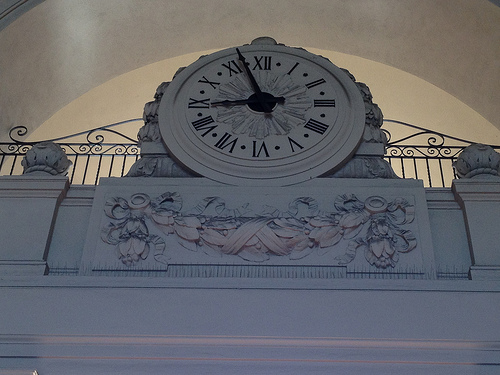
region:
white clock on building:
[185, 57, 335, 179]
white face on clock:
[171, 51, 336, 178]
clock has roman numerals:
[175, 57, 326, 179]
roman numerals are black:
[198, 53, 323, 175]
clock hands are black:
[195, 54, 315, 165]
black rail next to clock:
[365, 111, 469, 202]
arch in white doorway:
[8, 70, 479, 140]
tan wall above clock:
[8, 0, 469, 70]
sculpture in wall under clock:
[105, 161, 403, 276]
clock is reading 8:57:
[194, 57, 309, 167]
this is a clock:
[175, 38, 360, 174]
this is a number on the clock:
[277, 125, 306, 160]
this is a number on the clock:
[304, 111, 336, 139]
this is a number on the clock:
[309, 91, 351, 116]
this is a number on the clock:
[298, 73, 340, 93]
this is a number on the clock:
[281, 49, 308, 85]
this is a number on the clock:
[241, 42, 278, 82]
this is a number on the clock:
[217, 45, 247, 78]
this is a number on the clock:
[181, 90, 221, 115]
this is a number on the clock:
[211, 129, 238, 156]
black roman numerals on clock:
[183, 53, 335, 153]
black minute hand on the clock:
[233, 47, 272, 116]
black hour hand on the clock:
[203, 88, 283, 115]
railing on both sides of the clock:
[11, 120, 483, 177]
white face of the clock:
[183, 55, 357, 162]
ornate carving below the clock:
[104, 184, 414, 268]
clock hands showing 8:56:
[175, 44, 290, 121]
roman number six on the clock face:
[248, 138, 270, 161]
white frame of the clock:
[120, 38, 400, 185]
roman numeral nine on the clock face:
[185, 92, 212, 114]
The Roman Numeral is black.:
[220, 56, 245, 81]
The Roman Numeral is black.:
[191, 70, 222, 90]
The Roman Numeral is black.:
[178, 93, 215, 112]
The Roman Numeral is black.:
[186, 113, 220, 144]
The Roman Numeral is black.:
[211, 127, 241, 156]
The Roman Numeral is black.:
[249, 132, 272, 159]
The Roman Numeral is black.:
[307, 93, 341, 116]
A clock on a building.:
[156, 43, 367, 189]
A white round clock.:
[156, 42, 367, 191]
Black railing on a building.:
[0, 115, 499, 188]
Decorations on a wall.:
[97, 189, 419, 271]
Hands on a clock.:
[209, 45, 286, 122]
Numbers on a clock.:
[185, 50, 337, 159]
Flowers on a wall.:
[97, 188, 419, 271]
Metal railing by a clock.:
[1, 116, 498, 186]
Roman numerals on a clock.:
[186, 53, 336, 159]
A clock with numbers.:
[156, 43, 366, 189]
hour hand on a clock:
[202, 90, 277, 116]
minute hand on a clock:
[230, 38, 283, 124]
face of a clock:
[162, 38, 360, 191]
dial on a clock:
[248, 88, 278, 116]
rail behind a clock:
[1, 138, 495, 198]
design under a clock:
[96, 185, 430, 283]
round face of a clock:
[149, 34, 374, 195]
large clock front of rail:
[159, 28, 368, 185]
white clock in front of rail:
[158, 31, 371, 188]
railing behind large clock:
[2, 106, 498, 186]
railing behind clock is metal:
[2, 96, 499, 187]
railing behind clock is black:
[2, 100, 497, 190]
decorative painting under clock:
[90, 171, 429, 278]